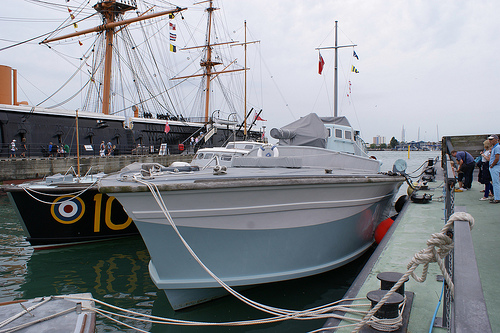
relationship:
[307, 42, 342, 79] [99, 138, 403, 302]
flag on top of boat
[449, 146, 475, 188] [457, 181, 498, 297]
man on top of dock